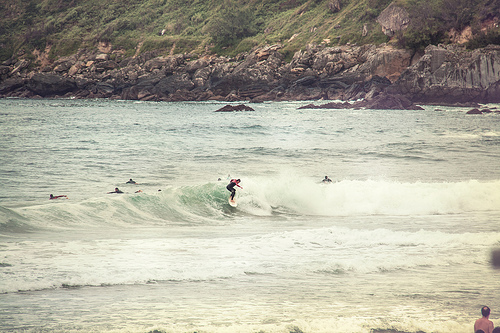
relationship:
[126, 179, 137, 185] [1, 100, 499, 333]
person in water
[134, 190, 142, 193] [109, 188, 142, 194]
leg of person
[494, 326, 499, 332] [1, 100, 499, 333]
woman by water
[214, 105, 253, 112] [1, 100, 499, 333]
rock in water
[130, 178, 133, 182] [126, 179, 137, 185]
head of person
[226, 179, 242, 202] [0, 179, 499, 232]
man riding wave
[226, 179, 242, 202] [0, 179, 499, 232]
man catching wave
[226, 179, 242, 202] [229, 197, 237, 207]
man riding board